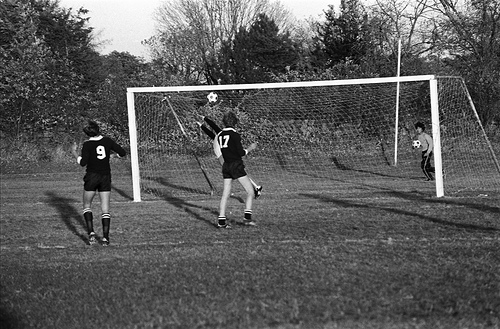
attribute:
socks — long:
[209, 190, 279, 227]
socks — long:
[78, 203, 115, 238]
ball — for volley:
[410, 138, 420, 150]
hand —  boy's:
[409, 143, 421, 150]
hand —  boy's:
[422, 152, 429, 157]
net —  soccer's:
[137, 76, 494, 208]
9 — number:
[90, 142, 109, 163]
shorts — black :
[200, 164, 280, 191]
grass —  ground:
[294, 208, 454, 281]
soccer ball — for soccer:
[190, 94, 274, 124]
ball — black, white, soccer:
[409, 138, 421, 151]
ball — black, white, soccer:
[206, 92, 218, 105]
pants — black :
[417, 155, 431, 177]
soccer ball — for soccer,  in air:
[204, 89, 220, 111]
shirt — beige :
[213, 134, 245, 168]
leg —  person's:
[215, 176, 233, 230]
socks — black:
[78, 204, 110, 237]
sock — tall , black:
[77, 205, 98, 240]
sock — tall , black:
[97, 209, 114, 240]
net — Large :
[127, 75, 499, 197]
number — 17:
[217, 132, 228, 147]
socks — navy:
[74, 207, 131, 229]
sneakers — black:
[85, 232, 115, 249]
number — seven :
[222, 134, 229, 146]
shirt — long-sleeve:
[74, 132, 125, 172]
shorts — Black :
[81, 177, 113, 194]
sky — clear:
[3, 7, 481, 98]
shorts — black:
[215, 159, 260, 182]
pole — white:
[428, 77, 450, 199]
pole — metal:
[415, 62, 468, 222]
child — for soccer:
[370, 110, 440, 207]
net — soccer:
[129, 67, 490, 205]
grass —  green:
[207, 249, 380, 321]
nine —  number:
[94, 142, 107, 159]